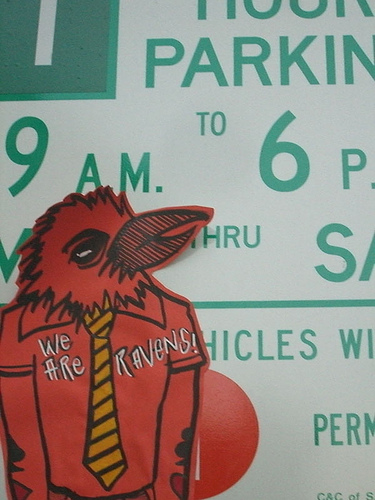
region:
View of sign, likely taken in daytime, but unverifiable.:
[7, 37, 367, 499]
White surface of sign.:
[116, 112, 171, 151]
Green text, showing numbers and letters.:
[9, 42, 325, 188]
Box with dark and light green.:
[1, 0, 124, 104]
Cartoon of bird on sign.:
[9, 196, 294, 498]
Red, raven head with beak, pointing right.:
[33, 194, 224, 304]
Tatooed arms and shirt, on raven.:
[4, 302, 211, 498]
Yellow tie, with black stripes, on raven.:
[87, 310, 134, 491]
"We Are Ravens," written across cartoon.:
[38, 330, 211, 381]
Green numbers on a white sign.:
[33, 144, 38, 164]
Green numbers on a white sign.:
[268, 149, 270, 166]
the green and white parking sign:
[0, 0, 374, 498]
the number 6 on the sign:
[259, 110, 309, 191]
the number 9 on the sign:
[5, 116, 48, 195]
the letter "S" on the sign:
[314, 223, 356, 281]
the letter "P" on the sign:
[312, 412, 326, 445]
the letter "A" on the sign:
[181, 37, 228, 86]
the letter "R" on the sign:
[233, 36, 269, 85]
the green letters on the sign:
[0, 0, 374, 499]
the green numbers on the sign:
[5, 110, 308, 196]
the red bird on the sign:
[0, 185, 213, 498]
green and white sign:
[25, 18, 361, 290]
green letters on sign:
[3, 20, 363, 405]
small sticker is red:
[12, 196, 220, 468]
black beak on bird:
[127, 203, 194, 277]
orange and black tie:
[69, 304, 111, 475]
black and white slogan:
[24, 332, 209, 380]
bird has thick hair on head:
[13, 194, 184, 329]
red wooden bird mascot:
[0, 185, 212, 498]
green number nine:
[6, 115, 49, 195]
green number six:
[257, 108, 310, 191]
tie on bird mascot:
[83, 293, 127, 491]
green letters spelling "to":
[197, 110, 227, 135]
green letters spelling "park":
[146, 35, 321, 86]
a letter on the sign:
[146, 32, 190, 93]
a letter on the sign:
[311, 414, 327, 444]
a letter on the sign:
[348, 416, 366, 451]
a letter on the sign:
[233, 323, 255, 355]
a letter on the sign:
[253, 326, 273, 362]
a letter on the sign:
[299, 328, 314, 356]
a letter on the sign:
[337, 322, 360, 363]